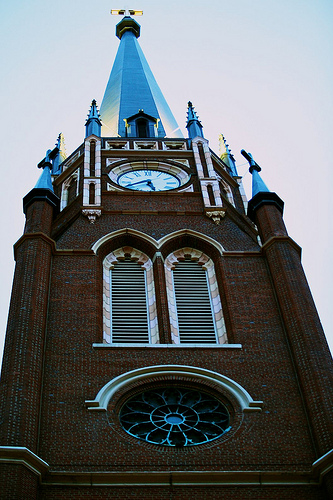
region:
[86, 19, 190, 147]
A tall blue cone on the building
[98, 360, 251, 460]
A large circular window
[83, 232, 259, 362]
Two windows with blinds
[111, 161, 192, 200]
A large clock on the building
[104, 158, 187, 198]
The clock says 5:40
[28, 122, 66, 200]
Small blue structure on the building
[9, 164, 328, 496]
A brown brick clocktower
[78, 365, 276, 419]
White trim on the window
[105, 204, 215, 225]
A small ledge on the building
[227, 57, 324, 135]
A clear sky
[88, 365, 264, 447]
ornate round paned window below the two arched windows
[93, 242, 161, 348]
arched window on the left side with tile border and slats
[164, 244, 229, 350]
arched window on the right side, identical to the one on the left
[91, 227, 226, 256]
arched eave above the two arched windows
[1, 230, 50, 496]
decorative column along the left side of the tower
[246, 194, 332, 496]
decorative column on the right side of the tower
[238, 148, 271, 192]
cross that sits atop the column on the right side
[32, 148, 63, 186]
cross that sits atop the column on the left side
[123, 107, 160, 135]
sculpture of Jesus Christ on top of the tower and at the base of the steeple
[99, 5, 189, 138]
metal steeple of the church with a gold cross on top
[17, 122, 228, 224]
Clock on the building.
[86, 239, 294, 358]
Windows on the building.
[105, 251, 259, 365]
Slats on the window.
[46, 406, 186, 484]
Stone on the building.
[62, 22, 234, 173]
Spire on the tower.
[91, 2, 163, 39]
Top of the spire.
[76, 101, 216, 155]
Roof on the building.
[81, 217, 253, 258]
Dormers over the window.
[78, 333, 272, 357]
Ledge of the window.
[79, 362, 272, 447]
Circular window on the building.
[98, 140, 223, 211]
Clock on front of tower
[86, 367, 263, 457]
Circular window with panes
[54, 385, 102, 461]
Building is made of brick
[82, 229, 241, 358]
Window with vents on it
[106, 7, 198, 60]
Steeple on top of building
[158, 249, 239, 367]
The window is surrounded by tile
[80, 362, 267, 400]
Arch over the window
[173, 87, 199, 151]
Steeple on the building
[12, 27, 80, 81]
Sky is blue no clouds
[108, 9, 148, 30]
Cross on top of the steeple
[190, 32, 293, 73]
Sky is blue color.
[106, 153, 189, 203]
Clock is attached to the tower.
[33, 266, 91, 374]
Tower is brown color.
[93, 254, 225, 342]
Windows are cream color.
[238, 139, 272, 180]
Cross symbol is in top of the tower.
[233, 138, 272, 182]
Cross is blue color.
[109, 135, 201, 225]
5.40 is the time shown.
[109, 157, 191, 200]
Clock is white and black color.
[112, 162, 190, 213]
Numbers are Roman letters.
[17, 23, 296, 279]
Day time picture.